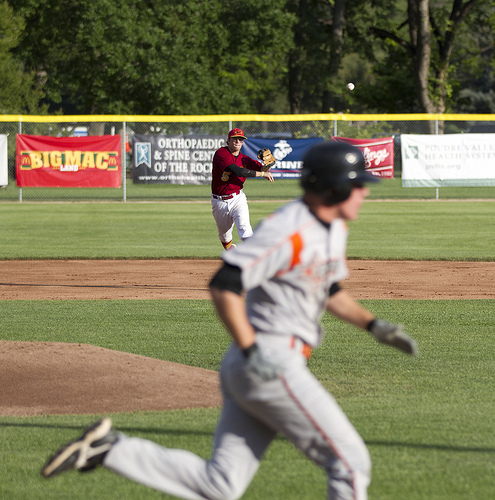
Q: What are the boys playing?
A: Baseball.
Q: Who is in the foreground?
A: The base runner.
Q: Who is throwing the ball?
A: The fielder.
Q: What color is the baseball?
A: White.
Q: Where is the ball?
A: In the air.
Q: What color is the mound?
A: Brown.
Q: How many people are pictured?
A: Two.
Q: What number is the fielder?
A: Five.